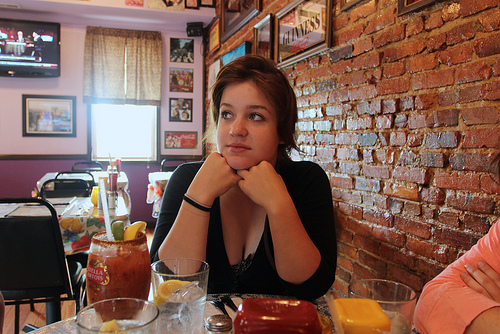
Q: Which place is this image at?
A: It is at the restaurant.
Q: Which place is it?
A: It is a restaurant.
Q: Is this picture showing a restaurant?
A: Yes, it is showing a restaurant.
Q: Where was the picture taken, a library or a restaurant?
A: It was taken at a restaurant.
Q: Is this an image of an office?
A: No, the picture is showing a restaurant.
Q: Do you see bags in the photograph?
A: No, there are no bags.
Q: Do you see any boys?
A: No, there are no boys.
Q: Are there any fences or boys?
A: No, there are no boys or fences.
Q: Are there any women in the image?
A: Yes, there is a woman.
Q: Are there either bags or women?
A: Yes, there is a woman.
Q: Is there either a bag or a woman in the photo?
A: Yes, there is a woman.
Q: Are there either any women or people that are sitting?
A: Yes, the woman is sitting.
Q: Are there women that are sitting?
A: Yes, there is a woman that is sitting.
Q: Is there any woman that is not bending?
A: Yes, there is a woman that is sitting.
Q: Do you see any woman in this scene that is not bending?
A: Yes, there is a woman that is sitting .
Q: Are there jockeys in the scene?
A: No, there are no jockeys.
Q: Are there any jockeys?
A: No, there are no jockeys.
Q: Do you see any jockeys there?
A: No, there are no jockeys.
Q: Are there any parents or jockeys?
A: No, there are no jockeys or parents.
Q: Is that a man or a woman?
A: That is a woman.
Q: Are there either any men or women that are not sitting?
A: No, there is a woman but she is sitting.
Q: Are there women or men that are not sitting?
A: No, there is a woman but she is sitting.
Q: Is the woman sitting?
A: Yes, the woman is sitting.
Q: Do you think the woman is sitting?
A: Yes, the woman is sitting.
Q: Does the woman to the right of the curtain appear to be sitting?
A: Yes, the woman is sitting.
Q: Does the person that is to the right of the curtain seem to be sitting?
A: Yes, the woman is sitting.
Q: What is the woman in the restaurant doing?
A: The woman is sitting.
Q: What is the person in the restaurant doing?
A: The woman is sitting.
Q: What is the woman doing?
A: The woman is sitting.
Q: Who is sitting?
A: The woman is sitting.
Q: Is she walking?
A: No, the woman is sitting.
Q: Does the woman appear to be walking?
A: No, the woman is sitting.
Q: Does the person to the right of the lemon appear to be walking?
A: No, the woman is sitting.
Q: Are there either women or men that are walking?
A: No, there is a woman but she is sitting.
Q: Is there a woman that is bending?
A: No, there is a woman but she is sitting.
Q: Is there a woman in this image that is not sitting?
A: No, there is a woman but she is sitting.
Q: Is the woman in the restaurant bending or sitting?
A: The woman is sitting.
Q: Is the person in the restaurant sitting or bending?
A: The woman is sitting.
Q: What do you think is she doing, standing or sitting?
A: The woman is sitting.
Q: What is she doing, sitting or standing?
A: The woman is sitting.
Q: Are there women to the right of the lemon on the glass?
A: Yes, there is a woman to the right of the lemon.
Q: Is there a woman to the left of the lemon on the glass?
A: No, the woman is to the right of the lemon.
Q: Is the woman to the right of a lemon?
A: Yes, the woman is to the right of a lemon.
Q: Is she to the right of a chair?
A: No, the woman is to the right of a lemon.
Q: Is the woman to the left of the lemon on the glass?
A: No, the woman is to the right of the lemon.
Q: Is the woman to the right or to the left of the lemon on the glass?
A: The woman is to the right of the lemon.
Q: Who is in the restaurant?
A: The woman is in the restaurant.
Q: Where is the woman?
A: The woman is in the restaurant.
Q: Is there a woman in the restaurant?
A: Yes, there is a woman in the restaurant.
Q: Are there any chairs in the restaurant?
A: No, there is a woman in the restaurant.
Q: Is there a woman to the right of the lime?
A: Yes, there is a woman to the right of the lime.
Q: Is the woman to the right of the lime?
A: Yes, the woman is to the right of the lime.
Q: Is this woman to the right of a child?
A: No, the woman is to the right of the lime.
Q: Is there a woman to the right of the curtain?
A: Yes, there is a woman to the right of the curtain.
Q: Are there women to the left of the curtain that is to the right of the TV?
A: No, the woman is to the right of the curtain.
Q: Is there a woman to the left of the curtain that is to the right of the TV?
A: No, the woman is to the right of the curtain.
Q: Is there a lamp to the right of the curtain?
A: No, there is a woman to the right of the curtain.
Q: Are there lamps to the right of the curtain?
A: No, there is a woman to the right of the curtain.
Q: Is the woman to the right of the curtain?
A: Yes, the woman is to the right of the curtain.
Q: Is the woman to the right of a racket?
A: No, the woman is to the right of the curtain.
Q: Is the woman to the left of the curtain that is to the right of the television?
A: No, the woman is to the right of the curtain.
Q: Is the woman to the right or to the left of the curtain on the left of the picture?
A: The woman is to the right of the curtain.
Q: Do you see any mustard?
A: Yes, there is mustard.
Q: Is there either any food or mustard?
A: Yes, there is mustard.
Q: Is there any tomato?
A: No, there are no tomatoes.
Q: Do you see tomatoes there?
A: No, there are no tomatoes.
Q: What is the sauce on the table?
A: The sauce is mustard.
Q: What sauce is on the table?
A: The sauce is mustard.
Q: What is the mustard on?
A: The mustard is on the table.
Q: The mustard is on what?
A: The mustard is on the table.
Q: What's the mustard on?
A: The mustard is on the table.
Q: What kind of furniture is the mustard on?
A: The mustard is on the table.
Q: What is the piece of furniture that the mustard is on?
A: The piece of furniture is a table.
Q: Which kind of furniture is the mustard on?
A: The mustard is on the table.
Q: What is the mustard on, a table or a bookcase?
A: The mustard is on a table.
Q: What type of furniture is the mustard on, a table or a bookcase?
A: The mustard is on a table.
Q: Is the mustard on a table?
A: Yes, the mustard is on a table.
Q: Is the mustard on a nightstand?
A: No, the mustard is on a table.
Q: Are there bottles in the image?
A: Yes, there is a bottle.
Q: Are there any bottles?
A: Yes, there is a bottle.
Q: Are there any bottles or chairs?
A: Yes, there is a bottle.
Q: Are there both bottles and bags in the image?
A: No, there is a bottle but no bags.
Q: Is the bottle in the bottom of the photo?
A: Yes, the bottle is in the bottom of the image.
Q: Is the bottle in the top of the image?
A: No, the bottle is in the bottom of the image.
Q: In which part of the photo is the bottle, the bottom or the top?
A: The bottle is in the bottom of the image.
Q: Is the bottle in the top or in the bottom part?
A: The bottle is in the bottom of the image.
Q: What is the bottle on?
A: The bottle is on the table.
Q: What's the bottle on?
A: The bottle is on the table.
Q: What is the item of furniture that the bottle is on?
A: The piece of furniture is a table.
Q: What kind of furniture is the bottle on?
A: The bottle is on the table.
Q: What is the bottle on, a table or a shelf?
A: The bottle is on a table.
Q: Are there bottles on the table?
A: Yes, there is a bottle on the table.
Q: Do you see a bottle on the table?
A: Yes, there is a bottle on the table.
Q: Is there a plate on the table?
A: No, there is a bottle on the table.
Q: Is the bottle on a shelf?
A: No, the bottle is on the table.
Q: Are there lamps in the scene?
A: No, there are no lamps.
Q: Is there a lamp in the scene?
A: No, there are no lamps.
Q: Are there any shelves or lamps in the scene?
A: No, there are no lamps or shelves.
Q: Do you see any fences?
A: No, there are no fences.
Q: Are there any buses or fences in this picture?
A: No, there are no fences or buses.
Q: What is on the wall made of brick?
A: The sign is on the wall.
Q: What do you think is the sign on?
A: The sign is on the wall.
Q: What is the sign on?
A: The sign is on the wall.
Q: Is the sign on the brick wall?
A: Yes, the sign is on the wall.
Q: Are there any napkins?
A: No, there are no napkins.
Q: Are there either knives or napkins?
A: No, there are no napkins or knives.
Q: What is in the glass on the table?
A: The straw is in the glass.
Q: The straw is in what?
A: The straw is in the glass.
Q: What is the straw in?
A: The straw is in the glass.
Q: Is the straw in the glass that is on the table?
A: Yes, the straw is in the glass.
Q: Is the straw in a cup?
A: No, the straw is in the glass.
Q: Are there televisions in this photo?
A: Yes, there is a television.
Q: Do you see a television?
A: Yes, there is a television.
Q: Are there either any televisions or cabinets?
A: Yes, there is a television.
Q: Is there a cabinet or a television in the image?
A: Yes, there is a television.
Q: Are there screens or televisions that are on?
A: Yes, the television is on.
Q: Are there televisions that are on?
A: Yes, there is a television that is on.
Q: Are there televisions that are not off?
A: Yes, there is a television that is on.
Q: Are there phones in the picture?
A: No, there are no phones.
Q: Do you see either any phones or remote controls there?
A: No, there are no phones or remote controls.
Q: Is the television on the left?
A: Yes, the television is on the left of the image.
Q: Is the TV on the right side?
A: No, the TV is on the left of the image.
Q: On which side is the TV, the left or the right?
A: The TV is on the left of the image.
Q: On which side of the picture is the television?
A: The television is on the left of the image.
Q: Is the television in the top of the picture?
A: Yes, the television is in the top of the image.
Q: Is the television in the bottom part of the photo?
A: No, the television is in the top of the image.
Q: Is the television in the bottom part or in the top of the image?
A: The television is in the top of the image.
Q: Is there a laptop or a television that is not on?
A: No, there is a television but it is on.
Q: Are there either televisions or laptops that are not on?
A: No, there is a television but it is on.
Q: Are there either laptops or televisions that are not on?
A: No, there is a television but it is on.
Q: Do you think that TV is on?
A: Yes, the TV is on.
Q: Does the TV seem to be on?
A: Yes, the TV is on.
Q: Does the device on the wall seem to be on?
A: Yes, the TV is on.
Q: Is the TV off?
A: No, the TV is on.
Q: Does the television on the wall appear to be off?
A: No, the TV is on.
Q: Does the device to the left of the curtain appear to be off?
A: No, the TV is on.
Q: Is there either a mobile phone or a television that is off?
A: No, there is a television but it is on.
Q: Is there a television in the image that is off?
A: No, there is a television but it is on.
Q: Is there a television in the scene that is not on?
A: No, there is a television but it is on.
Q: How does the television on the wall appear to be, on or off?
A: The TV is on.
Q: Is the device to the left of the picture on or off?
A: The TV is on.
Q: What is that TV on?
A: The TV is on the wall.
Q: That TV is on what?
A: The TV is on the wall.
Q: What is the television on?
A: The TV is on the wall.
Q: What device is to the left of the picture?
A: The device is a television.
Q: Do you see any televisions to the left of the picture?
A: Yes, there is a television to the left of the picture.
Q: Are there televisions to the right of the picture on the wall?
A: No, the television is to the left of the picture.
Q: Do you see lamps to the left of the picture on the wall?
A: No, there is a television to the left of the picture.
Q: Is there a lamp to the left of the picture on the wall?
A: No, there is a television to the left of the picture.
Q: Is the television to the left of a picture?
A: Yes, the television is to the left of a picture.